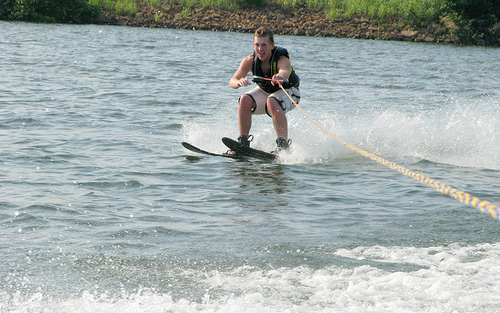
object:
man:
[222, 27, 301, 161]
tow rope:
[243, 75, 499, 225]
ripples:
[0, 21, 500, 312]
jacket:
[250, 46, 300, 93]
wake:
[0, 241, 500, 313]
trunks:
[238, 85, 303, 115]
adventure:
[0, 21, 499, 312]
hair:
[254, 26, 274, 44]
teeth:
[261, 51, 264, 53]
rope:
[241, 75, 500, 224]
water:
[0, 20, 500, 313]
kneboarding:
[181, 137, 293, 161]